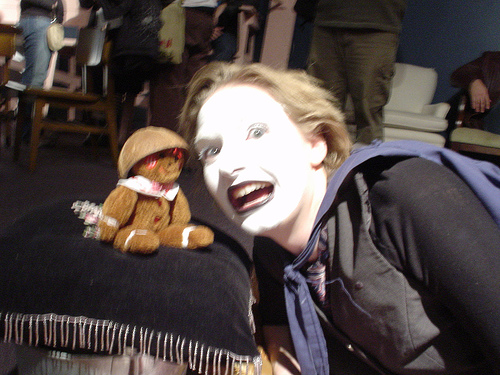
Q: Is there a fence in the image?
A: No, there are no fences.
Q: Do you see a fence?
A: No, there are no fences.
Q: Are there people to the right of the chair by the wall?
A: Yes, there are people to the right of the chair.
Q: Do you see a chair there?
A: Yes, there is a chair.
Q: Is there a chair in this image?
A: Yes, there is a chair.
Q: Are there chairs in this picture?
A: Yes, there is a chair.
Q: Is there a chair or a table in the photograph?
A: Yes, there is a chair.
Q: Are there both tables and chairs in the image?
A: No, there is a chair but no tables.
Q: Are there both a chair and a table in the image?
A: No, there is a chair but no tables.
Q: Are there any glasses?
A: No, there are no glasses.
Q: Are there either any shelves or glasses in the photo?
A: No, there are no glasses or shelves.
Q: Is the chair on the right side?
A: Yes, the chair is on the right of the image.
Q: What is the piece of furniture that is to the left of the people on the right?
A: The piece of furniture is a chair.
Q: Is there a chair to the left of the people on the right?
A: Yes, there is a chair to the left of the people.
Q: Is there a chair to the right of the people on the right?
A: No, the chair is to the left of the people.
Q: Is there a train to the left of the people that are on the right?
A: No, there is a chair to the left of the people.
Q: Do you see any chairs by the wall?
A: Yes, there is a chair by the wall.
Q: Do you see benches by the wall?
A: No, there is a chair by the wall.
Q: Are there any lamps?
A: No, there are no lamps.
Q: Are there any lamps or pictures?
A: No, there are no lamps or pictures.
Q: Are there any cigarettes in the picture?
A: No, there are no cigarettes.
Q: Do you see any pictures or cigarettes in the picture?
A: No, there are no cigarettes or pictures.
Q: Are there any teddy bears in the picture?
A: Yes, there is a teddy bear.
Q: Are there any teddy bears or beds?
A: Yes, there is a teddy bear.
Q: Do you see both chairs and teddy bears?
A: Yes, there are both a teddy bear and a chair.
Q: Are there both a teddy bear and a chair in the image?
A: Yes, there are both a teddy bear and a chair.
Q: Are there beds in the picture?
A: No, there are no beds.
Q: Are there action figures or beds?
A: No, there are no beds or action figures.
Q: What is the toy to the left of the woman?
A: The toy is a teddy bear.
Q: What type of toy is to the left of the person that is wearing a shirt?
A: The toy is a teddy bear.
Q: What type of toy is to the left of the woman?
A: The toy is a teddy bear.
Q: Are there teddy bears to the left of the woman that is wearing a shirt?
A: Yes, there is a teddy bear to the left of the woman.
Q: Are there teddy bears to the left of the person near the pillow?
A: Yes, there is a teddy bear to the left of the woman.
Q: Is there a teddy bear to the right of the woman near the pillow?
A: No, the teddy bear is to the left of the woman.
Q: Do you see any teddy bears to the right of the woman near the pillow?
A: No, the teddy bear is to the left of the woman.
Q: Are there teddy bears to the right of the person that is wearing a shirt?
A: No, the teddy bear is to the left of the woman.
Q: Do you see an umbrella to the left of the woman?
A: No, there is a teddy bear to the left of the woman.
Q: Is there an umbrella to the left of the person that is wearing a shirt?
A: No, there is a teddy bear to the left of the woman.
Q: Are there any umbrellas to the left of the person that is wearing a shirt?
A: No, there is a teddy bear to the left of the woman.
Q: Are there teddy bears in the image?
A: Yes, there is a teddy bear.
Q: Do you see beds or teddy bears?
A: Yes, there is a teddy bear.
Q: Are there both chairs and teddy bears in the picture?
A: Yes, there are both a teddy bear and a chair.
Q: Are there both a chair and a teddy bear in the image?
A: Yes, there are both a teddy bear and a chair.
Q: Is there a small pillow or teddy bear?
A: Yes, there is a small teddy bear.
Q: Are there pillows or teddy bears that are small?
A: Yes, the teddy bear is small.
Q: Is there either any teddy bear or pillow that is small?
A: Yes, the teddy bear is small.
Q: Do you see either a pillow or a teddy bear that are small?
A: Yes, the teddy bear is small.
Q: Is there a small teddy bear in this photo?
A: Yes, there is a small teddy bear.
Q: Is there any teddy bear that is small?
A: Yes, there is a teddy bear that is small.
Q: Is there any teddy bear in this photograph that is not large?
A: Yes, there is a small teddy bear.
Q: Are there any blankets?
A: No, there are no blankets.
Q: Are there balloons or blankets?
A: No, there are no blankets or balloons.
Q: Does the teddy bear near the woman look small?
A: Yes, the teddy bear is small.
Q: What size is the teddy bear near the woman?
A: The teddy bear is small.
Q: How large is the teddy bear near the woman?
A: The teddy bear is small.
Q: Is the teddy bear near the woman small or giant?
A: The teddy bear is small.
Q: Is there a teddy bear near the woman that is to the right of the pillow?
A: Yes, there is a teddy bear near the woman.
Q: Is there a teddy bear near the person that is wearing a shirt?
A: Yes, there is a teddy bear near the woman.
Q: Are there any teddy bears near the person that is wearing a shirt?
A: Yes, there is a teddy bear near the woman.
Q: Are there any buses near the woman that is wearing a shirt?
A: No, there is a teddy bear near the woman.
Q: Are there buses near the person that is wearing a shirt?
A: No, there is a teddy bear near the woman.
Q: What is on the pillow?
A: The teddy bear is on the pillow.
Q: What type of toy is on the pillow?
A: The toy is a teddy bear.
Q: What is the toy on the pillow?
A: The toy is a teddy bear.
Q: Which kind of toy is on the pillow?
A: The toy is a teddy bear.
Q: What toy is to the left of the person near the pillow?
A: The toy is a teddy bear.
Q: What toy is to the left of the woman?
A: The toy is a teddy bear.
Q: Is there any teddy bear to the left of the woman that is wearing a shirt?
A: Yes, there is a teddy bear to the left of the woman.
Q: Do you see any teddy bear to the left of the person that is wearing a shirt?
A: Yes, there is a teddy bear to the left of the woman.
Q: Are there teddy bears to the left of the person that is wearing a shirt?
A: Yes, there is a teddy bear to the left of the woman.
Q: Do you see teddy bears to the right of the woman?
A: No, the teddy bear is to the left of the woman.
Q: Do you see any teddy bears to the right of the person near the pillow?
A: No, the teddy bear is to the left of the woman.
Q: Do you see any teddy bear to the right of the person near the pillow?
A: No, the teddy bear is to the left of the woman.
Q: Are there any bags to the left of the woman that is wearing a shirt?
A: No, there is a teddy bear to the left of the woman.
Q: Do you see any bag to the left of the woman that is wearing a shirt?
A: No, there is a teddy bear to the left of the woman.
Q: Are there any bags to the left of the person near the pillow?
A: No, there is a teddy bear to the left of the woman.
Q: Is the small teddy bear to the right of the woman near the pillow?
A: No, the teddy bear is to the left of the woman.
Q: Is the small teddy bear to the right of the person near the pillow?
A: No, the teddy bear is to the left of the woman.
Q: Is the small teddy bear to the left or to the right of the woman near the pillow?
A: The teddy bear is to the left of the woman.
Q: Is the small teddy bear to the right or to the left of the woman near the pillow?
A: The teddy bear is to the left of the woman.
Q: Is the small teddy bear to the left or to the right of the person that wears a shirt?
A: The teddy bear is to the left of the woman.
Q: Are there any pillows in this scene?
A: Yes, there is a pillow.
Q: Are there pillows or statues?
A: Yes, there is a pillow.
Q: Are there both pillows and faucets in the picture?
A: No, there is a pillow but no faucets.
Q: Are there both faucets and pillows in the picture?
A: No, there is a pillow but no faucets.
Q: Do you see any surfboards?
A: No, there are no surfboards.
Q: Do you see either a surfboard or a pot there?
A: No, there are no surfboards or pots.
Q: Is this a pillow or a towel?
A: This is a pillow.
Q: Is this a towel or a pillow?
A: This is a pillow.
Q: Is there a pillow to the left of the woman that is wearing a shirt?
A: Yes, there is a pillow to the left of the woman.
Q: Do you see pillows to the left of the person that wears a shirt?
A: Yes, there is a pillow to the left of the woman.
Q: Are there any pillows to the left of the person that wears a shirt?
A: Yes, there is a pillow to the left of the woman.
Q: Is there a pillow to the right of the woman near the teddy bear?
A: No, the pillow is to the left of the woman.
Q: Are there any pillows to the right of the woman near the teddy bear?
A: No, the pillow is to the left of the woman.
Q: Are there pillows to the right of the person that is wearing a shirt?
A: No, the pillow is to the left of the woman.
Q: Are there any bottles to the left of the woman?
A: No, there is a pillow to the left of the woman.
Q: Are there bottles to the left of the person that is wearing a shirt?
A: No, there is a pillow to the left of the woman.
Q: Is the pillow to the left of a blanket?
A: No, the pillow is to the left of the woman.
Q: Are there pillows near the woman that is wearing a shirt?
A: Yes, there is a pillow near the woman.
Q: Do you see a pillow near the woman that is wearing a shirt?
A: Yes, there is a pillow near the woman.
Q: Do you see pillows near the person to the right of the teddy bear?
A: Yes, there is a pillow near the woman.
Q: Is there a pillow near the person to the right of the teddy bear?
A: Yes, there is a pillow near the woman.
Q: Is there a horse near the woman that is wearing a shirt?
A: No, there is a pillow near the woman.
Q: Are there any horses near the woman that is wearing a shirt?
A: No, there is a pillow near the woman.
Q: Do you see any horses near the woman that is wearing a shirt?
A: No, there is a pillow near the woman.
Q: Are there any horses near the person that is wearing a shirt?
A: No, there is a pillow near the woman.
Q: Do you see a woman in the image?
A: Yes, there is a woman.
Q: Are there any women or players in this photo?
A: Yes, there is a woman.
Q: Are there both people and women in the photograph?
A: Yes, there are both a woman and a person.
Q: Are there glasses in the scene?
A: No, there are no glasses.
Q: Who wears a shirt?
A: The woman wears a shirt.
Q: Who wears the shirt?
A: The woman wears a shirt.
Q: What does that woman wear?
A: The woman wears a shirt.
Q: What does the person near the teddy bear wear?
A: The woman wears a shirt.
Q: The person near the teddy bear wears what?
A: The woman wears a shirt.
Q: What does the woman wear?
A: The woman wears a shirt.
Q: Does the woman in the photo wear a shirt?
A: Yes, the woman wears a shirt.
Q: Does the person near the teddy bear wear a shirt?
A: Yes, the woman wears a shirt.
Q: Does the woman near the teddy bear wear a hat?
A: No, the woman wears a shirt.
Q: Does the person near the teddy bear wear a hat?
A: No, the woman wears a shirt.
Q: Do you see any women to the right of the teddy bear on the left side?
A: Yes, there is a woman to the right of the teddy bear.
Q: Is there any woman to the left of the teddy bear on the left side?
A: No, the woman is to the right of the teddy bear.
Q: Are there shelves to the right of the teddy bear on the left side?
A: No, there is a woman to the right of the teddy bear.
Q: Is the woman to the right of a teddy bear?
A: Yes, the woman is to the right of a teddy bear.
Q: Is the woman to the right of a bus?
A: No, the woman is to the right of a teddy bear.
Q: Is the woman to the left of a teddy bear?
A: No, the woman is to the right of a teddy bear.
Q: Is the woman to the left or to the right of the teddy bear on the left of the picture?
A: The woman is to the right of the teddy bear.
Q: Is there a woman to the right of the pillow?
A: Yes, there is a woman to the right of the pillow.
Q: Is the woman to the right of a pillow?
A: Yes, the woman is to the right of a pillow.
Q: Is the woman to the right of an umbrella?
A: No, the woman is to the right of a pillow.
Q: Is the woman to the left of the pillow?
A: No, the woman is to the right of the pillow.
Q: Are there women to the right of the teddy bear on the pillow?
A: Yes, there is a woman to the right of the teddy bear.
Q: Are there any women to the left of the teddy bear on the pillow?
A: No, the woman is to the right of the teddy bear.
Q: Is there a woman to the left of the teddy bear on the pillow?
A: No, the woman is to the right of the teddy bear.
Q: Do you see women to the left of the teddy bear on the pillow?
A: No, the woman is to the right of the teddy bear.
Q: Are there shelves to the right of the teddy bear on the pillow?
A: No, there is a woman to the right of the teddy bear.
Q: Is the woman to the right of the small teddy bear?
A: Yes, the woman is to the right of the teddy bear.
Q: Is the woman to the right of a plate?
A: No, the woman is to the right of the teddy bear.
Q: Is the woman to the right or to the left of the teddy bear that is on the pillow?
A: The woman is to the right of the teddy bear.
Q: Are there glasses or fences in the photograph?
A: No, there are no glasses or fences.